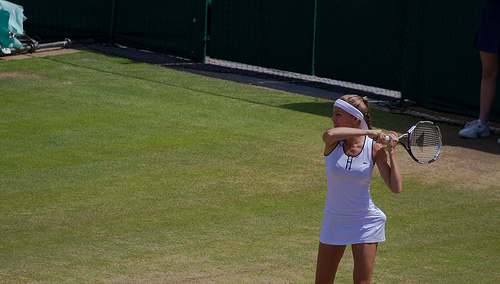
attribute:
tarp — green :
[0, 1, 26, 54]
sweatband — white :
[330, 96, 365, 121]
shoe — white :
[457, 116, 487, 143]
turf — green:
[1, 50, 495, 282]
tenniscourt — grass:
[3, 55, 498, 282]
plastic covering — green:
[2, 12, 32, 53]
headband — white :
[319, 93, 410, 138]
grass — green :
[6, 62, 288, 246]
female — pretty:
[303, 82, 465, 274]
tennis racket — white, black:
[370, 112, 450, 169]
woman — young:
[317, 92, 404, 282]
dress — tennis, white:
[286, 124, 444, 252]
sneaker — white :
[457, 114, 499, 149]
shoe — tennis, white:
[457, 119, 492, 141]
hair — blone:
[346, 109, 384, 131]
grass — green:
[7, 50, 496, 280]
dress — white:
[324, 138, 376, 235]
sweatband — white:
[337, 96, 362, 113]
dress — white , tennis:
[319, 130, 387, 244]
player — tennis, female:
[314, 91, 404, 281]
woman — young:
[316, 96, 397, 279]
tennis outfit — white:
[323, 125, 396, 248]